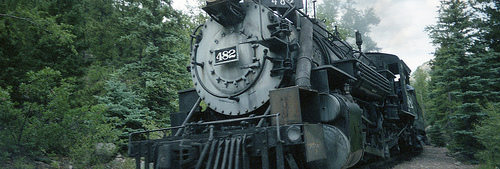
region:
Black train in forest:
[121, 0, 431, 167]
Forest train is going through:
[1, 0, 498, 167]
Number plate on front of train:
[212, 48, 240, 62]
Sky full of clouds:
[166, 0, 447, 77]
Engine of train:
[125, 0, 397, 168]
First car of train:
[360, 42, 430, 162]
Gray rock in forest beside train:
[91, 130, 120, 159]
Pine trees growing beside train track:
[422, 2, 497, 167]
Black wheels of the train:
[393, 141, 433, 161]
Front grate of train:
[121, 110, 285, 167]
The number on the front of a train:
[215, 46, 242, 65]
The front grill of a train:
[181, 126, 260, 166]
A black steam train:
[112, 2, 451, 167]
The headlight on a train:
[284, 121, 309, 150]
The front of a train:
[157, 5, 335, 167]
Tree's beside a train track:
[409, 0, 497, 146]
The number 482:
[212, 46, 239, 61]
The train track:
[356, 145, 428, 166]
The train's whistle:
[350, 29, 369, 56]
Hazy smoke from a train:
[311, 2, 445, 82]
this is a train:
[125, 13, 459, 163]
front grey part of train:
[171, 10, 313, 115]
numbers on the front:
[202, 48, 247, 61]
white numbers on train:
[212, 41, 246, 67]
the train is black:
[191, 18, 476, 161]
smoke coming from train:
[309, 1, 431, 52]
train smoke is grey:
[308, 2, 443, 59]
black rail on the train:
[120, 104, 270, 146]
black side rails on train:
[332, 42, 408, 93]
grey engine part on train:
[297, 64, 369, 156]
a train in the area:
[130, 3, 445, 161]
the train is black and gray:
[128, 4, 425, 167]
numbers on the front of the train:
[205, 48, 242, 63]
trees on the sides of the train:
[1, 0, 499, 163]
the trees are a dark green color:
[5, 3, 188, 168]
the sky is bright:
[163, 0, 448, 63]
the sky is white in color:
[175, 1, 446, 63]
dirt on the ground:
[410, 146, 457, 166]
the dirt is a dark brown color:
[400, 140, 466, 165]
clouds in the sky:
[366, 3, 436, 61]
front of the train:
[169, 16, 306, 161]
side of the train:
[366, 73, 421, 152]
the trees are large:
[74, 59, 137, 105]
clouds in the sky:
[405, 5, 427, 59]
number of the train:
[209, 41, 241, 71]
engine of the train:
[110, 128, 261, 163]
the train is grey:
[201, 78, 246, 111]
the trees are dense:
[440, 45, 475, 136]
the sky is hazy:
[407, 10, 428, 52]